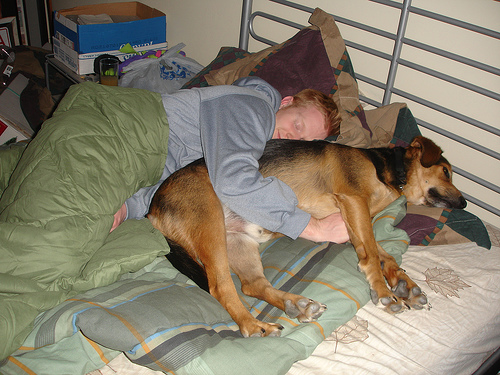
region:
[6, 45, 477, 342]
man and dog on a bed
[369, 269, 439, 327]
front paws of a dog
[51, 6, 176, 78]
box on a table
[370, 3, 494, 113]
metal headboard of a bed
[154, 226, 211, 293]
tail of a dog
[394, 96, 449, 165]
ears on a dog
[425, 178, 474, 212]
snout on a dog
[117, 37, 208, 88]
plastic bag on end table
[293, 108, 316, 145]
eyes of a man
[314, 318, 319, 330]
part of a mattress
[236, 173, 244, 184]
part of a sweater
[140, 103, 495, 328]
this is a large dog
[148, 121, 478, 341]
the dog is brown and black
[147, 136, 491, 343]
a dog is lying in bed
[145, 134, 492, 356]
the dog is on a bed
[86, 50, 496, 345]
the man is asleep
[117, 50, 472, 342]
a man and a dog sleeping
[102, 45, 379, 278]
the man is wearing a grey hoodie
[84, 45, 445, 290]
his arm is wrapped around the dog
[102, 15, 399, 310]
the man has his arm on the dog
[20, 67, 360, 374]
this is a green comforter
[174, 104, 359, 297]
a guy holding his dog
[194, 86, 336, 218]
a guy sleeping with his dog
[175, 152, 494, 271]
a dog sleeping with his human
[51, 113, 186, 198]
a blanket covering a man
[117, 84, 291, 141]
a man underneath a blanket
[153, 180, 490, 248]
a dog sleeping on top of a blanket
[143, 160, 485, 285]
a dog sleeping on top of a bed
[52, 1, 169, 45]
stuff inside a box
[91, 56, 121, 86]
a glass sitting next to a bed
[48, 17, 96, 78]
a box sitting on top of a table